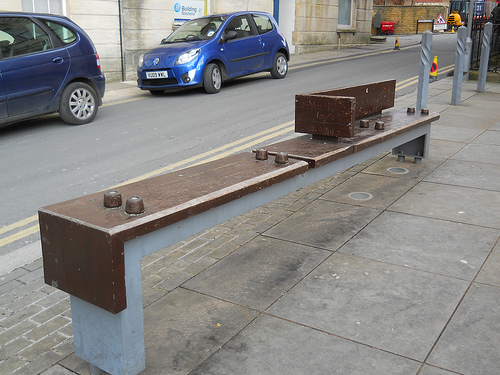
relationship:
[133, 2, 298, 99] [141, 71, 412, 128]
blue car on road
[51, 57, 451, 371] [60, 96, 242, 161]
bench on side of road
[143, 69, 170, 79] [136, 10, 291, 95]
number plate of blue car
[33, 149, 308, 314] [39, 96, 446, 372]
top of bench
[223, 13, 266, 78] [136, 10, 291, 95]
door of blue car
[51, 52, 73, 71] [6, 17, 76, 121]
handle of door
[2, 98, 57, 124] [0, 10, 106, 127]
dirt on bottom of blue car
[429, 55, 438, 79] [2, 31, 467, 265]
cone on road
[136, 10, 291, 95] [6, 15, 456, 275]
blue car parked on side of road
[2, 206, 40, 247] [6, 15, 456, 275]
lines on side of road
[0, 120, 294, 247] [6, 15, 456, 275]
lines on side of road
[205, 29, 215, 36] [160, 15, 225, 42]
sticker in window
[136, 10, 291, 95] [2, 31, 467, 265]
blue car parked on side of road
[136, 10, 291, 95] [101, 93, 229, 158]
blue car parked on side of road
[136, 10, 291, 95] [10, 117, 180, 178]
blue car parked on side of road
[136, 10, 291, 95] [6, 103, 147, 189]
blue car on street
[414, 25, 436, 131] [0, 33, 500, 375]
pole in road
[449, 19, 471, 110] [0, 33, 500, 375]
pole in road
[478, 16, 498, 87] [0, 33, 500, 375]
pole in road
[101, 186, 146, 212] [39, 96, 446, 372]
knobs on bench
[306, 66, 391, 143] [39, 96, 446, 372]
seat on bench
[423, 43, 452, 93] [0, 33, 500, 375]
cone on other side of road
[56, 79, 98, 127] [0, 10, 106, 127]
tire of blue car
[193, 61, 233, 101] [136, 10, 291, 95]
tire of blue car